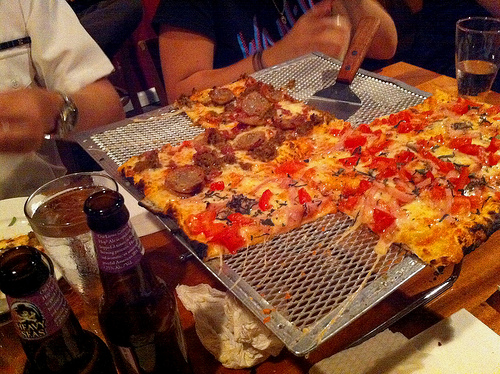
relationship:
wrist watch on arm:
[49, 85, 79, 141] [0, 90, 129, 152]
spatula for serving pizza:
[305, 13, 382, 118] [116, 73, 498, 272]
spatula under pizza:
[305, 13, 382, 118] [180, 72, 333, 132]